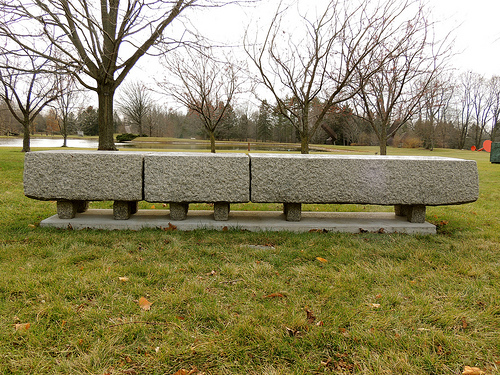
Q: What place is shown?
A: It is a field.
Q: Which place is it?
A: It is a field.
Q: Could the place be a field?
A: Yes, it is a field.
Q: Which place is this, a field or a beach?
A: It is a field.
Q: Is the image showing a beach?
A: No, the picture is showing a field.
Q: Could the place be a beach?
A: No, it is a field.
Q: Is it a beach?
A: No, it is a field.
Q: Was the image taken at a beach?
A: No, the picture was taken in a field.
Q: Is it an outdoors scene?
A: Yes, it is outdoors.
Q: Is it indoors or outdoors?
A: It is outdoors.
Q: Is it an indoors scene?
A: No, it is outdoors.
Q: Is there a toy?
A: No, there are no toys.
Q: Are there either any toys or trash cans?
A: No, there are no toys or trash cans.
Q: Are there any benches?
A: Yes, there is a bench.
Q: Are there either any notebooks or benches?
A: Yes, there is a bench.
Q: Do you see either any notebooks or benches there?
A: Yes, there is a bench.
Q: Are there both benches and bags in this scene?
A: No, there is a bench but no bags.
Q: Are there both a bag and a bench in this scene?
A: No, there is a bench but no bags.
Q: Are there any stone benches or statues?
A: Yes, there is a stone bench.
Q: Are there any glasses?
A: No, there are no glasses.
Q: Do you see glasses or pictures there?
A: No, there are no glasses or pictures.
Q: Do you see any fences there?
A: No, there are no fences.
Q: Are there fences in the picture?
A: No, there are no fences.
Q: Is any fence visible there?
A: No, there are no fences.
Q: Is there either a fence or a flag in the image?
A: No, there are no fences or flags.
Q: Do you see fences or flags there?
A: No, there are no fences or flags.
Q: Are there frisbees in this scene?
A: No, there are no frisbees.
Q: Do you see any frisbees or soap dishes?
A: No, there are no frisbees or soap dishes.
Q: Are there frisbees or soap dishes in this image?
A: No, there are no frisbees or soap dishes.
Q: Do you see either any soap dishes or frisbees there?
A: No, there are no frisbees or soap dishes.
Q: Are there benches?
A: Yes, there is a bench.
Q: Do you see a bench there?
A: Yes, there is a bench.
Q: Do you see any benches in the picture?
A: Yes, there is a bench.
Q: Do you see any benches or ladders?
A: Yes, there is a bench.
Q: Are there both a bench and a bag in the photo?
A: No, there is a bench but no bags.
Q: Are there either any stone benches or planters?
A: Yes, there is a stone bench.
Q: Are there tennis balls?
A: No, there are no tennis balls.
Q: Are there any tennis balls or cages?
A: No, there are no tennis balls or cages.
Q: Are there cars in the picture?
A: No, there are no cars.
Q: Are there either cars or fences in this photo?
A: No, there are no cars or fences.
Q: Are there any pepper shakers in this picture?
A: No, there are no pepper shakers.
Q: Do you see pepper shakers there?
A: No, there are no pepper shakers.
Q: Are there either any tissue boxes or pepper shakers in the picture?
A: No, there are no pepper shakers or tissue boxes.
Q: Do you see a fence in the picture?
A: No, there are no fences.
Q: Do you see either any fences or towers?
A: No, there are no fences or towers.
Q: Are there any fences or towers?
A: No, there are no fences or towers.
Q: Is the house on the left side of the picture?
A: Yes, the house is on the left of the image.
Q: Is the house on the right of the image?
A: No, the house is on the left of the image.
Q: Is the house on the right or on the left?
A: The house is on the left of the image.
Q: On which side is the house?
A: The house is on the left of the image.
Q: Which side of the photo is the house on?
A: The house is on the left of the image.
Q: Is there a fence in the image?
A: No, there are no fences.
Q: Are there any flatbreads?
A: No, there are no flatbreads.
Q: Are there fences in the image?
A: No, there are no fences.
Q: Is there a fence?
A: No, there are no fences.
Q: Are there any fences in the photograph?
A: No, there are no fences.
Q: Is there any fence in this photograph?
A: No, there are no fences.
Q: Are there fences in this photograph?
A: No, there are no fences.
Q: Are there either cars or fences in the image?
A: No, there are no fences or cars.